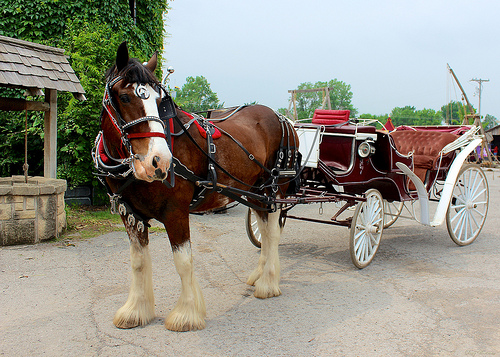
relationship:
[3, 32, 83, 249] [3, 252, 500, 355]
well on sidewalk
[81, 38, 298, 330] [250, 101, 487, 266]
horse pulling wagon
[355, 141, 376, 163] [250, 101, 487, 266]
horn on wagon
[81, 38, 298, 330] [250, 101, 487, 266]
horse attached to wagon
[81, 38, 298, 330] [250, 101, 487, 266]
horse strapped to wagon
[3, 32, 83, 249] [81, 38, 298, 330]
well next to horse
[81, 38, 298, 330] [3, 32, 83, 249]
horse next to well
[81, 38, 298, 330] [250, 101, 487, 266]
horse rigged up to wagon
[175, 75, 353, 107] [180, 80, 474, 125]
top of trees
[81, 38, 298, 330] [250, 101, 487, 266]
horse and wagon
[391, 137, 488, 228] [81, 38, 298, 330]
footpiece of horse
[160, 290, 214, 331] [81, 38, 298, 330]
foot of horse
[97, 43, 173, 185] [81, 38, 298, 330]
head of horse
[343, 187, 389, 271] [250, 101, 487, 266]
wheel on wagon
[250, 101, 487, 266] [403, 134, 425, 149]
wagon seat red